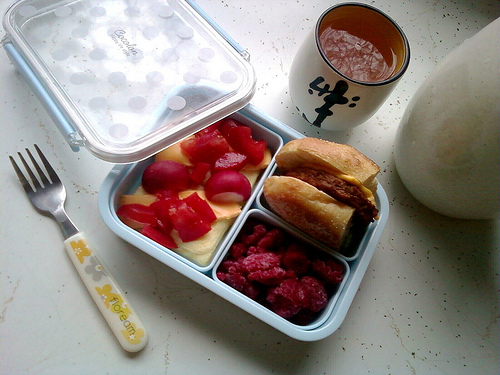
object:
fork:
[8, 142, 145, 357]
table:
[0, 0, 499, 375]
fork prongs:
[7, 142, 70, 241]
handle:
[63, 232, 148, 354]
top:
[2, 0, 256, 162]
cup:
[288, 3, 412, 131]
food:
[204, 167, 251, 199]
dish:
[91, 74, 390, 344]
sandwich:
[260, 136, 382, 253]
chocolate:
[317, 18, 395, 84]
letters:
[104, 24, 144, 62]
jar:
[396, 16, 499, 220]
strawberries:
[270, 279, 313, 318]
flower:
[66, 238, 91, 263]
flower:
[82, 256, 108, 286]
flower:
[94, 282, 115, 305]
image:
[296, 71, 357, 128]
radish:
[202, 167, 250, 206]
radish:
[142, 160, 190, 197]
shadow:
[99, 240, 328, 375]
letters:
[120, 325, 135, 336]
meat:
[263, 139, 379, 247]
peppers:
[115, 116, 266, 265]